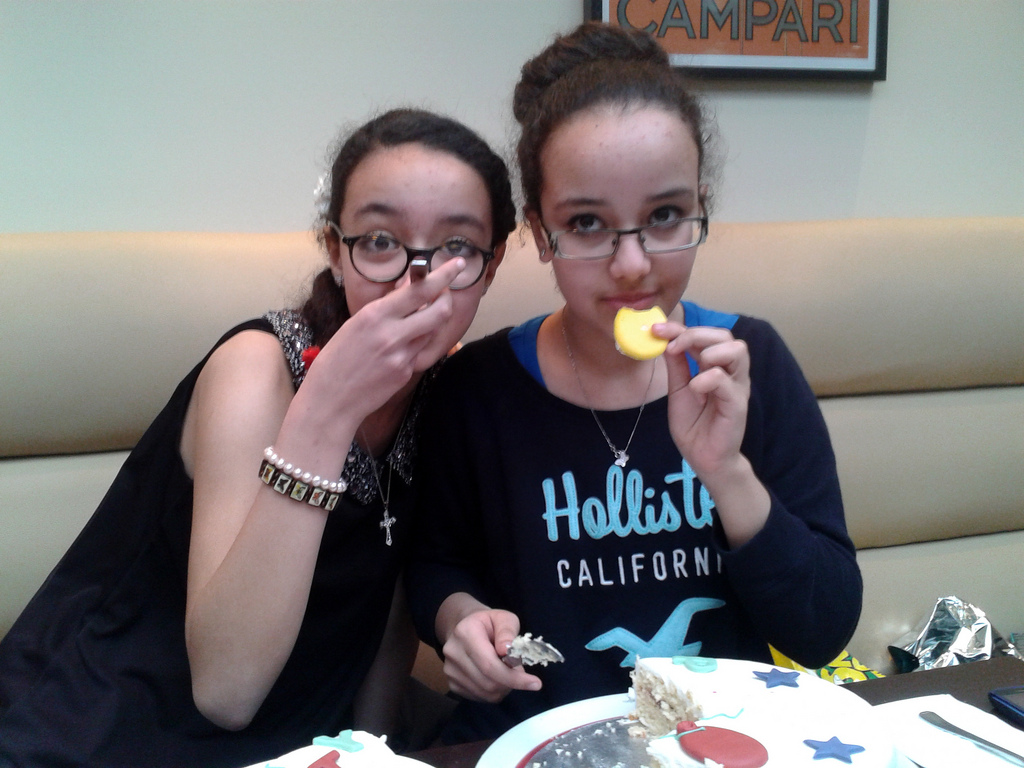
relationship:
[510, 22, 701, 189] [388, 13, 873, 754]
hair of girl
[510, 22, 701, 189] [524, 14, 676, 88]
hair in bun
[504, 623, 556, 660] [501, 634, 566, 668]
cake on cake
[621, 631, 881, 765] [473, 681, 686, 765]
cake on plate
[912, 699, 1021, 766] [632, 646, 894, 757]
utensil by cake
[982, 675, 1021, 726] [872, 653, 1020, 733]
cell phone on table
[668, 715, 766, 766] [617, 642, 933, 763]
circle on cake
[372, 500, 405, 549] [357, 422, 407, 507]
cross on chain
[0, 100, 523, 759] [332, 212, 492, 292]
girl wearing glasses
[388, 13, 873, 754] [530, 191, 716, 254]
girl wearing glasses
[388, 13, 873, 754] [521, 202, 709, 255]
girl wearing glasses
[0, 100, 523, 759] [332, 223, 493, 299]
girl wearing glasses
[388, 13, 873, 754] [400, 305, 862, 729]
girl wearing shirt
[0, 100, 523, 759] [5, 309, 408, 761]
girl wearing shirt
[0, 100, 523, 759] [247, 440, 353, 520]
girl wearing bracelet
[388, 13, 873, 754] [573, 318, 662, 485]
girl wearing necklace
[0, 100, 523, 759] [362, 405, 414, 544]
girl wearing necklace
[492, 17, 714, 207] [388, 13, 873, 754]
hair of girl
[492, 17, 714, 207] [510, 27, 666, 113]
hair in bun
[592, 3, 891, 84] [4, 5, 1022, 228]
picture on wall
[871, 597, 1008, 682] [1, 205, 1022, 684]
paper on bench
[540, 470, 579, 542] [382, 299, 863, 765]
letter on shirt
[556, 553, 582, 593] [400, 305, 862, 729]
letter on shirt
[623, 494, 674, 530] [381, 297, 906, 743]
letter on shirt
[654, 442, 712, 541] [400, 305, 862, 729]
letter on shirt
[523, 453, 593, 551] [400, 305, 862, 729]
letter on shirt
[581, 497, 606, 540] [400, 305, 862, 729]
letter on shirt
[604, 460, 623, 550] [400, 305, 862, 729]
letter on shirt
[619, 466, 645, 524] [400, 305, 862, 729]
letter on shirt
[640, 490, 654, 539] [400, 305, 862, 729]
letter on shirt